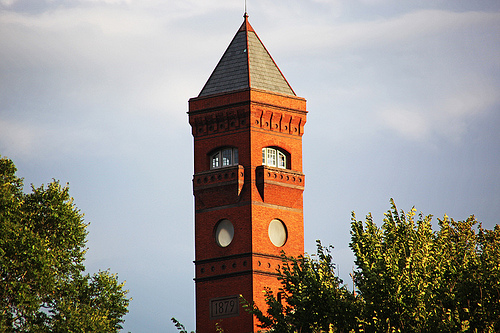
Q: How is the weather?
A: Cloudy.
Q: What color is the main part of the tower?
A: Orange.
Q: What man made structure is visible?
A: Tower.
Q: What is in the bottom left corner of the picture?
A: Tree.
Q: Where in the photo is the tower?
A: Center.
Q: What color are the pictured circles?
A: Beige.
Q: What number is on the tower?
A: 1879.